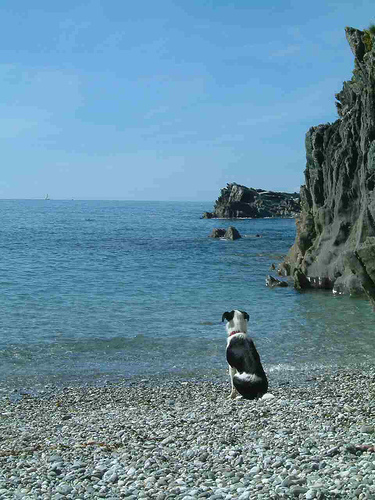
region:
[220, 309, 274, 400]
Dog sitting on rocky beach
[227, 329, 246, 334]
Red collar around dog's neck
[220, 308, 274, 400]
Dog looking out to sea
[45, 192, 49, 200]
Boat sailing near the horizon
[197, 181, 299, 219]
Large rock formation in the water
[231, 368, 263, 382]
White patch of fur on dog's back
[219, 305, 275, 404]
black and white dog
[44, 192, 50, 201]
sailboat in the distance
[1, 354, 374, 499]
rocky shore at a beach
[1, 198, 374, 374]
water in the ocean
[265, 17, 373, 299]
rock cliff at a beach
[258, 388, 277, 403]
tail of a dog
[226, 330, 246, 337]
a dog's red collar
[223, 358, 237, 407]
left front paw of a dog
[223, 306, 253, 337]
dog's head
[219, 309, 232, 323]
left ear of a dog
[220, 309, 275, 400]
the black and white dog sitting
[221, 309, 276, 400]
the white and black dog sitting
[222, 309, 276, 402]
the dog is sitting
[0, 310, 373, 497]
the rocks under the dog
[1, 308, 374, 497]
the rocks the dog is sitting on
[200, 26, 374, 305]
the large gray rocks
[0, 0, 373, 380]
the blue sky above the water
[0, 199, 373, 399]
the dog facing the large body of water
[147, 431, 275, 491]
A ground of rocky gray stones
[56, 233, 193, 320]
An area of blue rippling water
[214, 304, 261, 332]
A small dog's black and white head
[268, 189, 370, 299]
A rocky cliff-face in water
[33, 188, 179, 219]
Distant horizon of body of water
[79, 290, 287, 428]
A dog gazing out at the water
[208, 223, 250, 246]
Two rocks jutting from the water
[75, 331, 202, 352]
A light blue ripple of water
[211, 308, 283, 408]
black and white dog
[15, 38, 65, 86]
white clouds in blue sky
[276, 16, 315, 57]
white clouds in blue sky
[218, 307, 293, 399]
The black and white dog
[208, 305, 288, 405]
A black and white dog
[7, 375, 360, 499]
A rocky area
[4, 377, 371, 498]
The rocky area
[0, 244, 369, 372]
A body of water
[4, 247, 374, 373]
The body of water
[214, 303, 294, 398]
The dog on the beach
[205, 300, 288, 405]
A dog on the beach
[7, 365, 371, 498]
The rocky area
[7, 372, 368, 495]
A very rocky area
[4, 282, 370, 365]
The body of water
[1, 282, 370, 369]
A large body of water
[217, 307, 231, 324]
The left ear of the dog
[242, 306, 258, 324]
The right ear of the dog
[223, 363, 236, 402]
The front leg of the dog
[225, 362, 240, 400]
A front leg of the dog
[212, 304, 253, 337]
the head of a dog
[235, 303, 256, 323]
the right ear of a dog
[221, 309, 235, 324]
the left ear of a dog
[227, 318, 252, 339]
the neck of a dog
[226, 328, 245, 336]
the collar of a dog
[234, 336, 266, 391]
the back of a dog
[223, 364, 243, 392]
the front leg of a dog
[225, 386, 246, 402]
the hind leg of a dog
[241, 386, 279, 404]
the tail of a dog